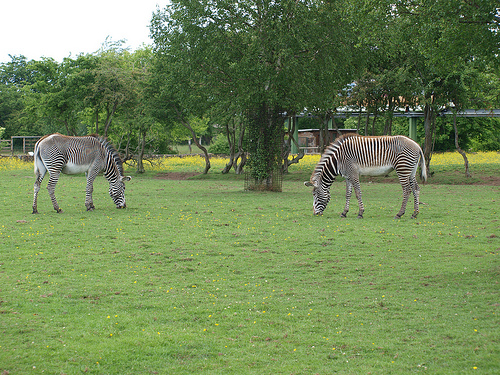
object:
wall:
[166, 144, 214, 158]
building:
[276, 77, 456, 154]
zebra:
[302, 132, 428, 219]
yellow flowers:
[145, 154, 256, 166]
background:
[1, 0, 500, 222]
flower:
[213, 280, 220, 283]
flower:
[195, 253, 199, 256]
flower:
[191, 254, 194, 257]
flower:
[213, 279, 220, 281]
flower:
[180, 288, 185, 290]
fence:
[0, 136, 41, 157]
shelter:
[280, 66, 500, 155]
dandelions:
[0, 148, 499, 171]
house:
[265, 77, 500, 155]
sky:
[0, 0, 497, 100]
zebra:
[32, 132, 132, 214]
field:
[0, 224, 499, 374]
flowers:
[472, 366, 477, 372]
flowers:
[474, 328, 478, 331]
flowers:
[414, 362, 430, 370]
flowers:
[293, 348, 297, 352]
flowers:
[380, 293, 387, 298]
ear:
[121, 176, 132, 183]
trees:
[132, 0, 366, 193]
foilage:
[244, 171, 284, 193]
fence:
[284, 127, 360, 155]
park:
[0, 0, 500, 375]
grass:
[0, 281, 500, 375]